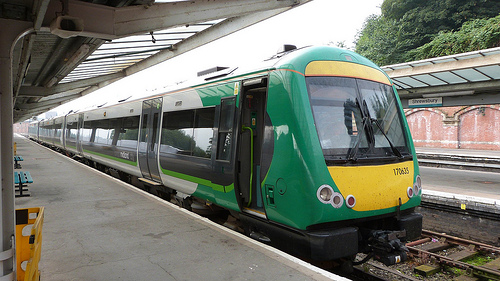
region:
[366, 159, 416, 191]
black numbers on atrain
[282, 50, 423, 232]
green and yellow train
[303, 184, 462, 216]
lights on a train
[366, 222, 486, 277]
rusted rail road tracks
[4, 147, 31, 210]
two blue benches by train stop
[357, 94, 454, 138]
a green and white sign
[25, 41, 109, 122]
light on a ceiling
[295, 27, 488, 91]
trees over top of roof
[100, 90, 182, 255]
gray doors on side of train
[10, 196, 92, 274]
yellow and black moving crates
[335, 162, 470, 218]
Yellow section on front of train.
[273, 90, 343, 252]
Green section on side of train.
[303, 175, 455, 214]
Lights on front of train.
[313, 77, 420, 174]
Large clear windshield on front of train.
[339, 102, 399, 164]
Wipers on front of train.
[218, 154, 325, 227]
Door is open on train.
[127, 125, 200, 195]
Doors in middle section of train.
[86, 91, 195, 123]
Gray color on top section of train.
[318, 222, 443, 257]
Front part of train is black.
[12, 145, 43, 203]
Benches on platform for train.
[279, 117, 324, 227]
green colored front of train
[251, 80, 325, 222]
green colored front of train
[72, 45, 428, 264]
a green yellow and white commuter train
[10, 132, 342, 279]
elevated train boarding platform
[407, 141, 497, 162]
elevated train boarding platform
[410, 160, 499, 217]
elevated train boarding platform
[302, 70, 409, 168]
a train front windshield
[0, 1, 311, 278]
a train station shelter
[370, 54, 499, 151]
a train station shelter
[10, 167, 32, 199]
a green wood bench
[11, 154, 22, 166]
a green wood bench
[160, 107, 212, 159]
a passenger train window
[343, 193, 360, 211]
headlight on front of train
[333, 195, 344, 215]
headlight on front of train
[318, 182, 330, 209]
headlight on front of train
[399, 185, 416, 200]
headlight on front of train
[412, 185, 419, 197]
headlight on front of train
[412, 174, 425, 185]
headlight on front of train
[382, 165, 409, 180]
number on front of train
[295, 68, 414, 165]
windshield on front of train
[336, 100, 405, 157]
wipers on front of train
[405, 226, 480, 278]
tracks under train